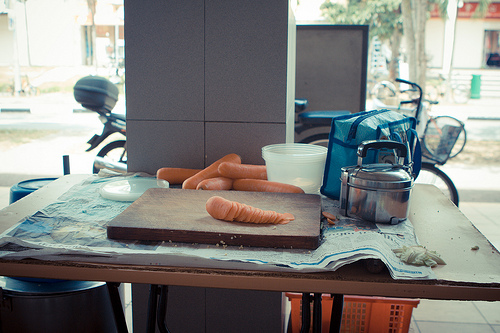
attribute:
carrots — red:
[155, 152, 307, 224]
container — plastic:
[258, 138, 333, 192]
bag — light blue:
[319, 106, 423, 198]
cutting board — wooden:
[110, 184, 323, 248]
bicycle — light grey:
[393, 79, 465, 165]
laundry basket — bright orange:
[285, 291, 420, 332]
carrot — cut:
[206, 194, 292, 225]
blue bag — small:
[318, 108, 421, 200]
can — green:
[462, 70, 484, 102]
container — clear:
[260, 141, 330, 195]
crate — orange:
[287, 292, 424, 331]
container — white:
[259, 141, 325, 201]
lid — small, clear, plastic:
[97, 167, 173, 204]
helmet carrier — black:
[69, 67, 121, 131]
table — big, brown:
[9, 183, 497, 301]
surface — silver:
[326, 160, 468, 264]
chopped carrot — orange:
[207, 195, 295, 223]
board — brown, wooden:
[107, 185, 321, 248]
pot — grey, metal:
[339, 141, 414, 226]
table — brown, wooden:
[41, 122, 493, 306]